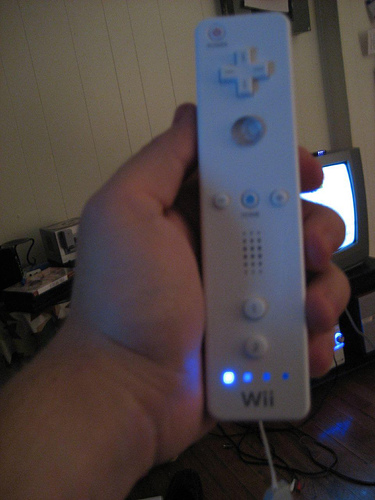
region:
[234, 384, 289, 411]
He is holding a Wii.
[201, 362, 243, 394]
The light is blue.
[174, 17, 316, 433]
The remote is white.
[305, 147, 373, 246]
The TV is on.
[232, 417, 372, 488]
The cords are on the floor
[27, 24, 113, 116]
The wall is tan.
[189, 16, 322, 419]
The buttons are white.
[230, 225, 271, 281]
There is a speaker on the remote.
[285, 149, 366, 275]
The TV is small.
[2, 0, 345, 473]
He is playing Wii.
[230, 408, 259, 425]
edge of a remote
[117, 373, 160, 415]
part of a wrist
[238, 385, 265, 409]
part of a graphic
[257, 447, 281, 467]
part of a wire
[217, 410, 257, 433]
edge of a remote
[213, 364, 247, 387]
part of a light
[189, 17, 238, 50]
power button on the remote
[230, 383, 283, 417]
letters on the remote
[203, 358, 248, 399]
blue light on remote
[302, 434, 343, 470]
wire on the ground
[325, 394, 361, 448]
light hitting the ground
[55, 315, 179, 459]
wrist of the person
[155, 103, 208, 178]
thumb of the person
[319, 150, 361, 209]
light from the television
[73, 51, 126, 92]
wall behind the television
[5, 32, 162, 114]
lines on the wall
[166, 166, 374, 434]
Someone is holding a Wii controller.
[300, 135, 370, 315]
The television is turned on.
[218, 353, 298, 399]
The controller is turned on.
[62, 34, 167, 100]
The wall is white.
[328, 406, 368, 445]
The floor is wooden.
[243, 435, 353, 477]
There are wires on the floor.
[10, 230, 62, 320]
The table is cluttered.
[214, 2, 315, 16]
A picture hangs above the television.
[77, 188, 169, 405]
The controller is held in a left hand.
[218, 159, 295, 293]
The controller is white.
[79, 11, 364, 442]
man holding a gaming controller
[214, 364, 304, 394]
blue led lights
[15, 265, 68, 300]
a book on a shelf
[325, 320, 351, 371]
a gaming console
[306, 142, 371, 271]
a TV on an entertainment unit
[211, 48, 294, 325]
various buttons on a gaming controller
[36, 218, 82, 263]
a cardboard box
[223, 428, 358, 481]
a bunch of wires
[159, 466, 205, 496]
a black shoe on the floor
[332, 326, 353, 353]
a blue led light on a gaming console